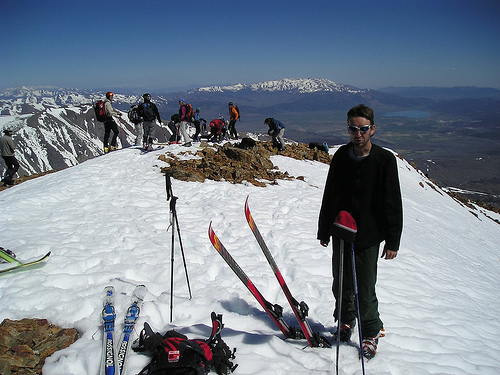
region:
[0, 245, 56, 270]
green colored skis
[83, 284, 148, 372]
blue skis flat in the snow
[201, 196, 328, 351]
red and orange skis vertical in the snow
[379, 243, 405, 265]
left hand of the man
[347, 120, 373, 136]
glasses on the man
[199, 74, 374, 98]
snow capped mountians in the distance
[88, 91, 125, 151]
man with an orange helmet and back pack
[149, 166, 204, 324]
vertical ski poles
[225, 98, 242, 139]
man in an orange jacket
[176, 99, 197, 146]
man with a blue hat and red back pack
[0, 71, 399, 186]
Snow capped mountains in the distance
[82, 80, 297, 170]
Skiers at the top of a moutain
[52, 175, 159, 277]
Tracks in the white snow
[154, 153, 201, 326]
Grey ski poles standing in the snow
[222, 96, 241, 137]
Skier in an orange jacket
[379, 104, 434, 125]
Lake in the background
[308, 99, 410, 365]
Man in ski boots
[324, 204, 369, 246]
Red winter hat resting on ski poles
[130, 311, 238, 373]
Black and red backpack laying in snow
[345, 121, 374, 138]
Man wearing silver ski goggles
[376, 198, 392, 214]
part of a coat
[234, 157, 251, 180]
edge of a rock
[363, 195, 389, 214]
part of a sweater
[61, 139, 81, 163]
part of a mountain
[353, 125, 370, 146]
face of a man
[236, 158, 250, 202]
edge of a rock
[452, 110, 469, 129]
part of a plain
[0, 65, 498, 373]
moutain are tall and rocky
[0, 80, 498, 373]
moutains are coverd in snow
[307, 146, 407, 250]
the person is wearing a jacket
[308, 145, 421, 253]
the jacket is black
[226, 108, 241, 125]
the jacket is orange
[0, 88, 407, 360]
eleven people are in the shot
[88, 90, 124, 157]
person is wearing black and red backpack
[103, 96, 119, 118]
the person has a grey jacket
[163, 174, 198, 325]
the skis are in the snow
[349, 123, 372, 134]
person is wearing gogoles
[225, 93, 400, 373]
a skier posing for a picture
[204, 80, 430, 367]
a man standing in the snow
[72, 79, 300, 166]
skiers gathered on a mountainside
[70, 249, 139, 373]
blue and white skis in the snow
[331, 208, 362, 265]
a red hat on top of two skis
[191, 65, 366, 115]
a snow caped mountain in the distance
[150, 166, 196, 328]
two ski poles in the snow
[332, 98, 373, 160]
a man wearing goggles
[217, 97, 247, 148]
a person wearing an orange shirt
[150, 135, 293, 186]
some brown rocks on the mountain